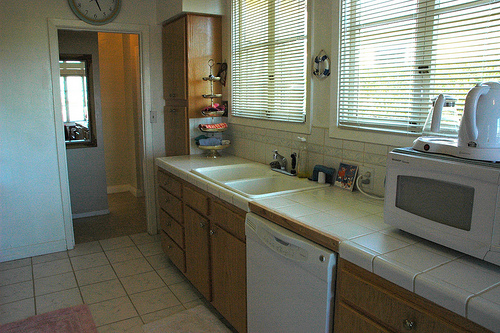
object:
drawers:
[159, 172, 185, 199]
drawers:
[153, 233, 190, 272]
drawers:
[336, 267, 460, 331]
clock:
[66, 1, 122, 25]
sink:
[190, 161, 329, 200]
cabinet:
[155, 152, 500, 332]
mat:
[0, 302, 96, 333]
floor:
[0, 231, 235, 331]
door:
[53, 28, 149, 246]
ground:
[2, 230, 235, 332]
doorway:
[47, 22, 152, 240]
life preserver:
[312, 50, 331, 80]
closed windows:
[334, 1, 500, 134]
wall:
[219, 7, 496, 185]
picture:
[335, 163, 357, 190]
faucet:
[290, 152, 297, 176]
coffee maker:
[459, 80, 500, 161]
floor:
[4, 229, 208, 331]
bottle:
[296, 136, 309, 179]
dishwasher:
[243, 212, 340, 332]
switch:
[150, 110, 157, 123]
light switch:
[148, 111, 157, 124]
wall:
[2, 0, 166, 259]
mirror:
[58, 58, 88, 140]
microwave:
[382, 147, 500, 267]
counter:
[152, 146, 499, 331]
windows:
[224, 0, 309, 126]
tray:
[203, 75, 220, 81]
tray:
[203, 93, 224, 99]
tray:
[201, 110, 225, 117]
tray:
[198, 127, 228, 133]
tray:
[198, 144, 231, 150]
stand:
[195, 59, 230, 158]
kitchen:
[4, 0, 500, 333]